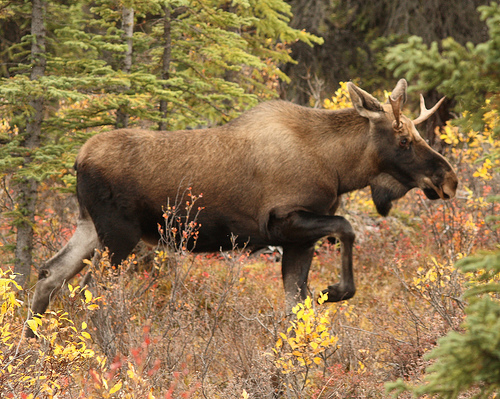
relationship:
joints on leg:
[325, 211, 361, 298] [276, 209, 359, 304]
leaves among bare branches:
[0, 185, 444, 397] [168, 282, 273, 397]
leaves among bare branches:
[0, 185, 444, 397] [338, 279, 421, 388]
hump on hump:
[249, 89, 347, 140] [230, 100, 299, 122]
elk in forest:
[25, 78, 457, 337] [23, 23, 173, 108]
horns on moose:
[340, 72, 441, 128] [51, 102, 463, 321]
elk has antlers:
[337, 68, 449, 135] [375, 88, 457, 130]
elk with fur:
[25, 78, 457, 337] [180, 152, 228, 174]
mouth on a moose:
[424, 177, 444, 199] [28, 80, 463, 314]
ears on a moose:
[352, 80, 414, 125] [15, 50, 487, 302]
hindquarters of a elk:
[22, 132, 131, 337] [25, 78, 457, 337]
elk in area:
[25, 78, 457, 337] [1, 40, 482, 395]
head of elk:
[351, 86, 458, 213] [25, 78, 457, 337]